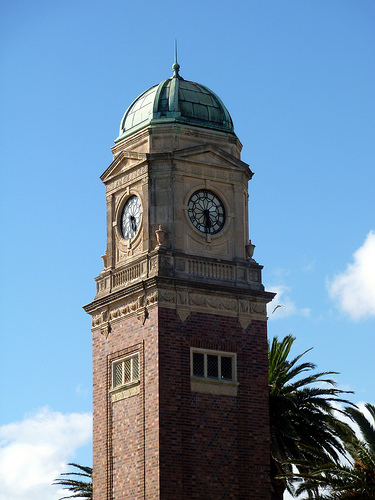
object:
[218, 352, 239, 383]
window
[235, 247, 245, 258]
stone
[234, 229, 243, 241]
stone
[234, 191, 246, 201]
stone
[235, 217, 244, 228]
stone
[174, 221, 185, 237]
stone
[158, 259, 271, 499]
wall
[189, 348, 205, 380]
window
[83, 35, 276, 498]
building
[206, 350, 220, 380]
window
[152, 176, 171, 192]
stone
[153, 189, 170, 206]
stone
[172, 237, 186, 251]
stone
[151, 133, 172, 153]
stone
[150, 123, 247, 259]
wall